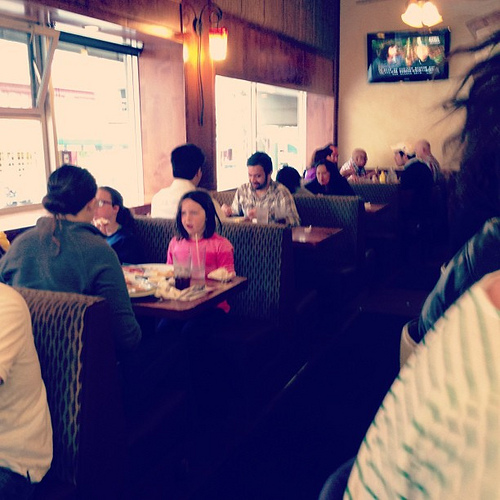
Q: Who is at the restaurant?
A: People.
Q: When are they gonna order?
A: When the waitress comes.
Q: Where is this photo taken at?
A: A restaurant.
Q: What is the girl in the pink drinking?
A: Water.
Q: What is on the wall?
A: A tv.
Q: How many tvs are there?
A: 1.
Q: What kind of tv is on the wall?
A: Flat screen.